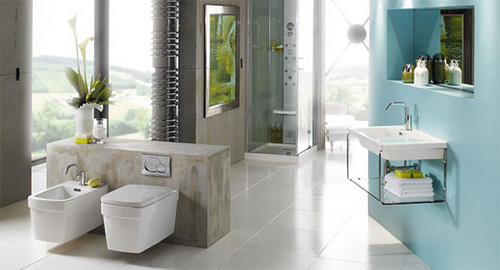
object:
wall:
[364, 0, 495, 268]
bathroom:
[0, 0, 495, 267]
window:
[313, 3, 374, 128]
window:
[109, 3, 154, 140]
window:
[30, 2, 97, 163]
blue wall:
[368, 0, 498, 269]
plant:
[65, 18, 112, 142]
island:
[43, 135, 229, 247]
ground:
[355, 174, 444, 204]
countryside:
[33, 42, 142, 153]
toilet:
[98, 178, 178, 255]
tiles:
[0, 146, 367, 267]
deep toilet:
[28, 178, 175, 255]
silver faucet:
[63, 163, 88, 188]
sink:
[337, 103, 447, 206]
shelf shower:
[260, 46, 298, 141]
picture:
[205, 3, 240, 115]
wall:
[181, 2, 248, 166]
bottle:
[413, 56, 429, 86]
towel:
[382, 175, 431, 198]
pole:
[148, 0, 174, 144]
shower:
[240, 1, 316, 153]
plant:
[63, 15, 115, 110]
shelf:
[350, 171, 444, 205]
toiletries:
[398, 51, 464, 85]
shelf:
[376, 69, 488, 104]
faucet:
[384, 102, 414, 126]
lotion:
[412, 56, 432, 85]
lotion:
[386, 61, 439, 131]